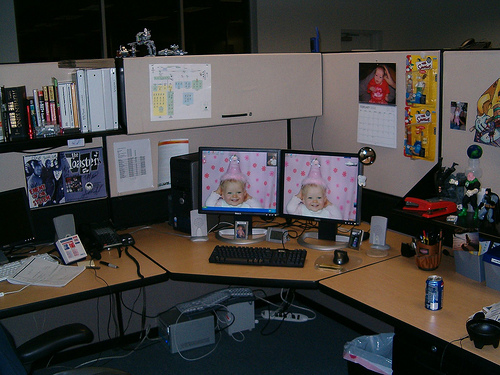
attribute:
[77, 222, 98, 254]
handset — black, telephone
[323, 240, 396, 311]
computer mouse — black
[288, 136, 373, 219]
monitor — small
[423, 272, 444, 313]
can — blue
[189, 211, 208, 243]
speaker — computer, gray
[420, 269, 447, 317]
can — aluminum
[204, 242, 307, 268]
keyboard — black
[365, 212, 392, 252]
speaker — small, grey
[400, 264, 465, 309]
can — aluminum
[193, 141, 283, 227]
monitor — small, computer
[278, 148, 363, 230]
monitor — small, computer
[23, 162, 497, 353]
desk — brown, wood, corner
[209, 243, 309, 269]
keyboard — black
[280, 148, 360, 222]
screen — single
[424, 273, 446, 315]
can — cola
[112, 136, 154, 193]
list — telephone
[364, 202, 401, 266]
computer speaker — gray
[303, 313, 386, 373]
trash can — lined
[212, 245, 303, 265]
keyboard — black, computer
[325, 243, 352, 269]
mouse — wireless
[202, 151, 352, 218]
pictures — baby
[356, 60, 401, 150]
calendar — colorful